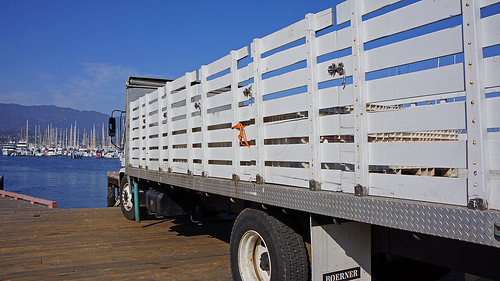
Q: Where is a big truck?
A: On the shore.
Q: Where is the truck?
A: On the dock.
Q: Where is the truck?
A: On front the sea.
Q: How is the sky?
A: Blue.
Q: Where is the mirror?
A: On left side.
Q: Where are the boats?
A: Inn the ocean.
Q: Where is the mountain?
A: Behind the boats?.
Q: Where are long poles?
A: On the boats.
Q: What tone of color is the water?
A: Color blue.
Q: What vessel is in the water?
A: A boat.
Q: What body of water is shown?
A: A lake.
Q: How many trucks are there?
A: One.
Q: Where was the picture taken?
A: At a pier.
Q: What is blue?
A: Water.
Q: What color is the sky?
A: Blue.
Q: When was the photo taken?
A: Daytime.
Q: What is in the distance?
A: Mountains.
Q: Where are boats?
A: In the water.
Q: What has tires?
A: A truck.